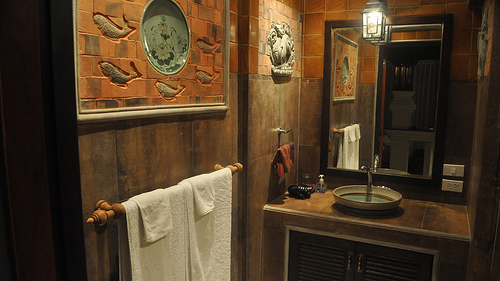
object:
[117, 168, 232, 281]
washcloths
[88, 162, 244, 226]
towel rack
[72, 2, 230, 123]
picture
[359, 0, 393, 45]
light fixture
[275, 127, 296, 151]
towel rack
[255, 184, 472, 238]
countertop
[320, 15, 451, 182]
mirror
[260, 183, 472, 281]
cabinet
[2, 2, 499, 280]
bathroom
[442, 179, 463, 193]
electrical outlets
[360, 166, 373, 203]
faucet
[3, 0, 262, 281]
wall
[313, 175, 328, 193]
soap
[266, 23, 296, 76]
sculpture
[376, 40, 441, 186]
window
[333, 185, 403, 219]
basin